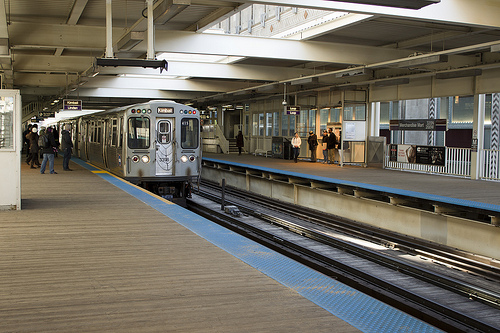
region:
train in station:
[37, 92, 204, 196]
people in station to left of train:
[23, 118, 75, 175]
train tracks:
[174, 172, 499, 332]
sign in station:
[388, 116, 445, 131]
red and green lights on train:
[126, 105, 201, 114]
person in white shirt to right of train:
[289, 131, 302, 159]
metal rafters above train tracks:
[66, 26, 482, 104]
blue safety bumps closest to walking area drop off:
[68, 150, 498, 332]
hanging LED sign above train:
[93, 51, 165, 73]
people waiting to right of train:
[287, 127, 340, 162]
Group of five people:
[273, 117, 353, 173]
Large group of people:
[11, 114, 88, 178]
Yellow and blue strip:
[81, 166, 243, 274]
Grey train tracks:
[150, 173, 415, 330]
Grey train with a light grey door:
[92, 95, 218, 204]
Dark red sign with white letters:
[365, 91, 480, 174]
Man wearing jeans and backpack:
[36, 125, 60, 175]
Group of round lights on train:
[124, 103, 156, 120]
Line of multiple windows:
[243, 101, 372, 158]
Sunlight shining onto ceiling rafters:
[59, 14, 359, 131]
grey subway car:
[93, 97, 209, 194]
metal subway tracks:
[278, 199, 338, 238]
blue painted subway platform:
[151, 188, 320, 311]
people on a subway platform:
[28, 120, 92, 162]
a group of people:
[276, 125, 350, 159]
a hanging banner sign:
[384, 110, 451, 135]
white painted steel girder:
[173, 28, 310, 63]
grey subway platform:
[60, 210, 140, 296]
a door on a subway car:
[152, 114, 180, 175]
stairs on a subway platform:
[211, 105, 254, 161]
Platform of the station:
[19, 225, 167, 315]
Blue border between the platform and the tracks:
[316, 281, 356, 313]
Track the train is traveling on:
[280, 229, 322, 254]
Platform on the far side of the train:
[366, 169, 426, 186]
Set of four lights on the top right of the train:
[176, 107, 201, 119]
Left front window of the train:
[126, 116, 156, 153]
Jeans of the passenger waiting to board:
[37, 153, 59, 176]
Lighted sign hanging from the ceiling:
[56, 98, 84, 113]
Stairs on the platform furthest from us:
[222, 135, 244, 155]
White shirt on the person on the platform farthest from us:
[290, 134, 305, 148]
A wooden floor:
[4, 213, 142, 319]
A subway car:
[68, 97, 203, 184]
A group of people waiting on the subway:
[25, 122, 82, 177]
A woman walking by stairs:
[208, 107, 249, 157]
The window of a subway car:
[126, 111, 156, 153]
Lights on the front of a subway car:
[126, 149, 156, 166]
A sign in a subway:
[56, 96, 92, 113]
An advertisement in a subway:
[383, 136, 454, 173]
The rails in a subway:
[211, 173, 483, 300]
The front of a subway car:
[122, 97, 206, 184]